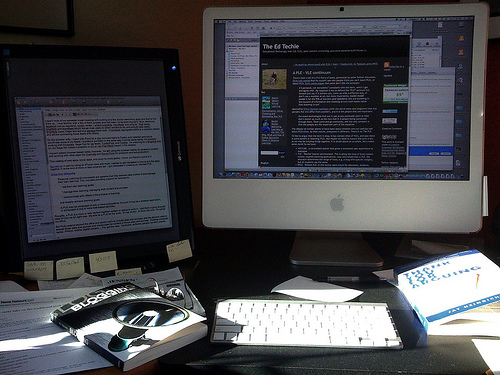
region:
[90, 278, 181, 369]
A book is visible.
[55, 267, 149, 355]
A book is visible.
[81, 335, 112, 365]
A book is visible.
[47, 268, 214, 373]
A book is visible.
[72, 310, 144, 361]
A book is visible.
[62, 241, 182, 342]
A book is visible.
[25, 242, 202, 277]
post-it notes on the edge of a computer monitor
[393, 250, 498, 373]
a white and blue book on a desk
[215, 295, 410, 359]
a white keyboard on a desk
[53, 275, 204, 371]
a book about blogging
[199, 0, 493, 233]
a white computer monitor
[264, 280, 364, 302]
a sheet of white paper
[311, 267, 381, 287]
a sharpie pen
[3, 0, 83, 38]
a framed document on the wall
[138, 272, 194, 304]
a pair of glasses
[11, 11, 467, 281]
two computer monitors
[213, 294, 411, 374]
white computer keyboard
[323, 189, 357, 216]
apple logo on front of monitor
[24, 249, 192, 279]
sticky notes across bottom of monitor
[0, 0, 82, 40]
painting hanging on wall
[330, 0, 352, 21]
camera on front of computer monitor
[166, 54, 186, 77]
power light on side of monitor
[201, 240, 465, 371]
sun shining on computer desk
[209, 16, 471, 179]
website showing on computer monitor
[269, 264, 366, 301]
piece of white paper laying on desk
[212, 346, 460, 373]
black computer desk top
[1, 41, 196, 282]
a black monitor screen with sticky notes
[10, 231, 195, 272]
the notes are yellow on the frame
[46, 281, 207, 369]
a book is lying on the table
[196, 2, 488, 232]
a screen with a white frame is on the table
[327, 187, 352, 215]
an apple is on the frame of the screen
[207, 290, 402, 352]
a white keyboard is on the table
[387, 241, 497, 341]
a blue and white book is on the table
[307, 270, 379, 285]
a black marker is below the screen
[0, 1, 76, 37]
a picture frame is on the wall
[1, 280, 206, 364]
papers are under the book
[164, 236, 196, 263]
a post-it note on a monitor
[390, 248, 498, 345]
a blue and white book on a desk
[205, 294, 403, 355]
a keyboard on a desk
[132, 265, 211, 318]
a pair of glasses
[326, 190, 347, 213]
an Apple logo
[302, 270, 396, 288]
a pen on a desk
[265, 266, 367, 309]
a white piece of paper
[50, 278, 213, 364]
a black and white book on a stack of paper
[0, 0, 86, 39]
a picture on a wall